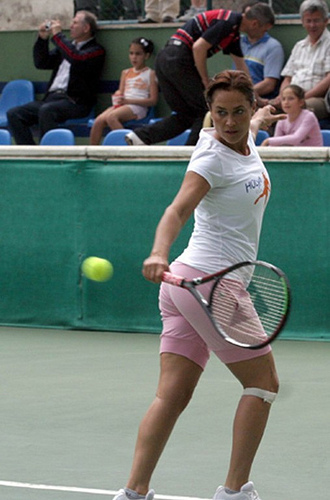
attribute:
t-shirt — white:
[174, 129, 272, 284]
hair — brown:
[199, 68, 259, 103]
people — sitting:
[38, 7, 318, 135]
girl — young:
[106, 31, 178, 143]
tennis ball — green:
[76, 255, 125, 287]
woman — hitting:
[172, 66, 311, 385]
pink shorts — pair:
[153, 255, 273, 371]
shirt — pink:
[272, 108, 320, 141]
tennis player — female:
[105, 66, 289, 491]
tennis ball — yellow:
[81, 256, 114, 282]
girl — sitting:
[89, 35, 159, 148]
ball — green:
[79, 246, 143, 304]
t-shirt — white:
[172, 128, 278, 280]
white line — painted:
[2, 477, 213, 497]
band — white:
[240, 386, 277, 404]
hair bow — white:
[138, 38, 148, 48]